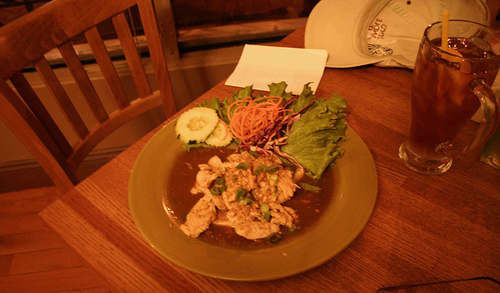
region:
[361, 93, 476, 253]
Brown table with a glass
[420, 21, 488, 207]
Glass on a table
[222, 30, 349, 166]
White paper on a table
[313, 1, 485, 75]
Hat sitting on a table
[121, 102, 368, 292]
Plate full of food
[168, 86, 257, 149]
Cucumbers on a plate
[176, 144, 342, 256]
Meat on a plate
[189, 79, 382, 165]
Salad on a plate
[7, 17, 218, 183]
Brown chair by a table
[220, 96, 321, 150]
Carrots on a salad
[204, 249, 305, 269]
this is a plate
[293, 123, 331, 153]
this is a vegetable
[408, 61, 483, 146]
this is a glass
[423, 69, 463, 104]
the has a liquid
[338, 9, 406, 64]
this is a cap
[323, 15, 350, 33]
the cap is white in color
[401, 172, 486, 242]
this is a table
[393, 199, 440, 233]
the table is brown in color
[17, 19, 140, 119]
this is a chair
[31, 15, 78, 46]
the chair is wooden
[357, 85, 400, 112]
part of a table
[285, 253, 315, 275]
edge of a plate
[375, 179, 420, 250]
part of a table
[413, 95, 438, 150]
part of a glass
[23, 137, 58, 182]
edge of a chair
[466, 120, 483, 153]
part of a handle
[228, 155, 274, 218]
part of a food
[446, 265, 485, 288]
part of a handle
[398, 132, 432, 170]
base of a glass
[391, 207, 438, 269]
part of a shade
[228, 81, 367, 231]
Green lettuce on side of plate.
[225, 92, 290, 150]
Orange food on top of lettuce.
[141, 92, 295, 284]
Food inside of greenish colored dish.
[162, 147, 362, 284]
Dish is sitting on wood table.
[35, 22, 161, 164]
Wood chair is near table.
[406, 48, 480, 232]
Brown liquid inside of clear glass.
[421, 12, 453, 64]
Glass has a straw in it.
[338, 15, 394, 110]
Hat sitting on top of table.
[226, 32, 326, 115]
White beverage napkin on table.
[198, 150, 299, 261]
Green onions on top of food.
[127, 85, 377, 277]
Meal on brown plate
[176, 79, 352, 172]
salad with shredded carrot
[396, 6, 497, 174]
Iced tea in glass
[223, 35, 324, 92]
White paper on table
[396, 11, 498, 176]
Iced tea with straw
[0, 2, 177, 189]
Wooden chair at table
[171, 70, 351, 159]
salad with cucumber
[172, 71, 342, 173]
Salad with carrots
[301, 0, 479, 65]
White cap on table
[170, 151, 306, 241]
Chicken on brown plate